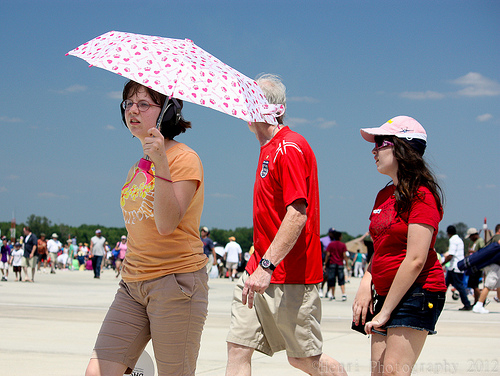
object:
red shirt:
[368, 182, 446, 292]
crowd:
[0, 225, 126, 283]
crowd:
[199, 223, 254, 279]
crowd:
[318, 230, 369, 300]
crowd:
[434, 223, 498, 312]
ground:
[0, 262, 497, 375]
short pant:
[95, 263, 208, 374]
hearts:
[133, 48, 143, 56]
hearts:
[187, 60, 198, 70]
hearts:
[230, 95, 243, 103]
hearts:
[120, 56, 132, 65]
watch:
[256, 256, 274, 275]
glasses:
[118, 100, 163, 110]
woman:
[82, 80, 209, 375]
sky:
[0, 3, 497, 235]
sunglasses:
[371, 136, 391, 152]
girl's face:
[370, 137, 397, 173]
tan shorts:
[226, 274, 328, 361]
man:
[220, 70, 343, 375]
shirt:
[243, 124, 325, 285]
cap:
[360, 114, 425, 143]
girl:
[352, 115, 446, 375]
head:
[359, 114, 429, 174]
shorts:
[224, 270, 323, 358]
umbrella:
[65, 30, 276, 146]